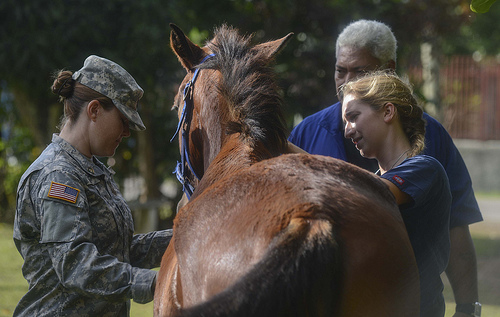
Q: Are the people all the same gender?
A: No, they are both male and female.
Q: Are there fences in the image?
A: Yes, there is a fence.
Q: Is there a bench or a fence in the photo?
A: Yes, there is a fence.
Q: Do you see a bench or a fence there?
A: Yes, there is a fence.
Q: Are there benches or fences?
A: Yes, there is a fence.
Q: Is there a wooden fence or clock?
A: Yes, there is a wood fence.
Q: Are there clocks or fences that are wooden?
A: Yes, the fence is wooden.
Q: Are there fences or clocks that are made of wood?
A: Yes, the fence is made of wood.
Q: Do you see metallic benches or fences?
A: Yes, there is a metal fence.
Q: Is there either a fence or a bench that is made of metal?
A: Yes, the fence is made of metal.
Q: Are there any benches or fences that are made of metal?
A: Yes, the fence is made of metal.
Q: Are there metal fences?
A: Yes, there is a fence that is made of metal.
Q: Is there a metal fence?
A: Yes, there is a fence that is made of metal.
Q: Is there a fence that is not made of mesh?
A: Yes, there is a fence that is made of metal.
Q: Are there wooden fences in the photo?
A: Yes, there is a wood fence.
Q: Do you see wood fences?
A: Yes, there is a wood fence.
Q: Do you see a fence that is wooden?
A: Yes, there is a fence that is wooden.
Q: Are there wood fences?
A: Yes, there is a fence that is made of wood.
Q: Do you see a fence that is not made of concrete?
A: Yes, there is a fence that is made of wood.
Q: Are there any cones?
A: No, there are no cones.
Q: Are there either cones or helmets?
A: No, there are no cones or helmets.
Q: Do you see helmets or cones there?
A: No, there are no cones or helmets.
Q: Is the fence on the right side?
A: Yes, the fence is on the right of the image.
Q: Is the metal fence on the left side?
A: No, the fence is on the right of the image.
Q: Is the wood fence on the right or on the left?
A: The fence is on the right of the image.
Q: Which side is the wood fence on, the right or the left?
A: The fence is on the right of the image.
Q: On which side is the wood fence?
A: The fence is on the right of the image.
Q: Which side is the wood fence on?
A: The fence is on the right of the image.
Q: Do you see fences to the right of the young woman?
A: Yes, there is a fence to the right of the woman.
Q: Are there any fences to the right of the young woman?
A: Yes, there is a fence to the right of the woman.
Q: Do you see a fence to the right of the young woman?
A: Yes, there is a fence to the right of the woman.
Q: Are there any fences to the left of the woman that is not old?
A: No, the fence is to the right of the woman.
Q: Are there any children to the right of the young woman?
A: No, there is a fence to the right of the woman.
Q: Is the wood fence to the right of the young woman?
A: Yes, the fence is to the right of the woman.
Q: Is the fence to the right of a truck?
A: No, the fence is to the right of the woman.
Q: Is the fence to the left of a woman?
A: No, the fence is to the right of a woman.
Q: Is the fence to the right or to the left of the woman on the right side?
A: The fence is to the right of the woman.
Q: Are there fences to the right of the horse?
A: Yes, there is a fence to the right of the horse.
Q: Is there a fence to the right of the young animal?
A: Yes, there is a fence to the right of the horse.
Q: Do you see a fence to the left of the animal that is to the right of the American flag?
A: No, the fence is to the right of the horse.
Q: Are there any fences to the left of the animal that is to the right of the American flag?
A: No, the fence is to the right of the horse.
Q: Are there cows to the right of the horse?
A: No, there is a fence to the right of the horse.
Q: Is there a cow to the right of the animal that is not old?
A: No, there is a fence to the right of the horse.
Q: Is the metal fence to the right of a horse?
A: Yes, the fence is to the right of a horse.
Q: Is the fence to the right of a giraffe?
A: No, the fence is to the right of a horse.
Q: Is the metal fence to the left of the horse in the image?
A: No, the fence is to the right of the horse.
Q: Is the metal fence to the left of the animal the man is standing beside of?
A: No, the fence is to the right of the horse.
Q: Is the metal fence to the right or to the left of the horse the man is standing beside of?
A: The fence is to the right of the horse.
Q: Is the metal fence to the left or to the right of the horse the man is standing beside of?
A: The fence is to the right of the horse.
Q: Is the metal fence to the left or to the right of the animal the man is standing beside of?
A: The fence is to the right of the horse.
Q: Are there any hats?
A: Yes, there is a hat.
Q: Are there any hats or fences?
A: Yes, there is a hat.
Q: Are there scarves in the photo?
A: No, there are no scarves.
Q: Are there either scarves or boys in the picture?
A: No, there are no scarves or boys.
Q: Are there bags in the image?
A: No, there are no bags.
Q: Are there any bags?
A: No, there are no bags.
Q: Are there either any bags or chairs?
A: No, there are no bags or chairs.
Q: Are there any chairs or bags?
A: No, there are no bags or chairs.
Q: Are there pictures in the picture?
A: No, there are no pictures.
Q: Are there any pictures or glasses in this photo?
A: No, there are no pictures or glasses.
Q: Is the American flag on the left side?
A: Yes, the American flag is on the left of the image.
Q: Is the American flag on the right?
A: No, the American flag is on the left of the image.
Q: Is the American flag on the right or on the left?
A: The American flag is on the left of the image.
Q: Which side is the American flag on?
A: The American flag is on the left of the image.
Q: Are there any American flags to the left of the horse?
A: Yes, there is an American flag to the left of the horse.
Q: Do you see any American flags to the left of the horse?
A: Yes, there is an American flag to the left of the horse.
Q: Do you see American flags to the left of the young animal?
A: Yes, there is an American flag to the left of the horse.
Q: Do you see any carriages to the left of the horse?
A: No, there is an American flag to the left of the horse.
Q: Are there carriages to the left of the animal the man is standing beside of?
A: No, there is an American flag to the left of the horse.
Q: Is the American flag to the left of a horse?
A: Yes, the American flag is to the left of a horse.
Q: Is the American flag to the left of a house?
A: No, the American flag is to the left of a horse.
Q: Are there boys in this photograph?
A: No, there are no boys.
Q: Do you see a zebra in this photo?
A: No, there are no zebras.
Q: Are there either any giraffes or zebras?
A: No, there are no zebras or giraffes.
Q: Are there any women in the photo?
A: Yes, there is a woman.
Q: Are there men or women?
A: Yes, there is a woman.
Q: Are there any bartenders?
A: No, there are no bartenders.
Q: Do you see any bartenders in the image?
A: No, there are no bartenders.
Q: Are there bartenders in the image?
A: No, there are no bartenders.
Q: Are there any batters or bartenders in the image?
A: No, there are no bartenders or batters.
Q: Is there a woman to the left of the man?
A: Yes, there is a woman to the left of the man.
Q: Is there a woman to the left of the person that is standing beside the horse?
A: Yes, there is a woman to the left of the man.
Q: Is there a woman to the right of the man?
A: No, the woman is to the left of the man.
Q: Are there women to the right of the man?
A: No, the woman is to the left of the man.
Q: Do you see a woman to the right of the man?
A: No, the woman is to the left of the man.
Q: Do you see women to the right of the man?
A: No, the woman is to the left of the man.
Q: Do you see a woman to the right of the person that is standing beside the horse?
A: No, the woman is to the left of the man.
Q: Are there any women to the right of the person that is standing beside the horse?
A: No, the woman is to the left of the man.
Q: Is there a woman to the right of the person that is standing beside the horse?
A: No, the woman is to the left of the man.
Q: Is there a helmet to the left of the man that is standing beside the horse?
A: No, there is a woman to the left of the man.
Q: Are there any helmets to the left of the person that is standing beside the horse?
A: No, there is a woman to the left of the man.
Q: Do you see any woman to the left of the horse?
A: Yes, there is a woman to the left of the horse.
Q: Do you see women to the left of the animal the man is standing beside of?
A: Yes, there is a woman to the left of the horse.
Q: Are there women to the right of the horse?
A: No, the woman is to the left of the horse.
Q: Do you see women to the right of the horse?
A: No, the woman is to the left of the horse.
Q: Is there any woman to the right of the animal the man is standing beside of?
A: No, the woman is to the left of the horse.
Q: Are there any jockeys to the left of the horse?
A: No, there is a woman to the left of the horse.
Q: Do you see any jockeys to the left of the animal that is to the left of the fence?
A: No, there is a woman to the left of the horse.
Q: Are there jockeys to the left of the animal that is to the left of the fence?
A: No, there is a woman to the left of the horse.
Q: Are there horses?
A: Yes, there is a horse.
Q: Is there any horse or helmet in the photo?
A: Yes, there is a horse.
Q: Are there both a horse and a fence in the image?
A: Yes, there are both a horse and a fence.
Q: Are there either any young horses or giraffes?
A: Yes, there is a young horse.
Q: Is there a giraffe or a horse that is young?
A: Yes, the horse is young.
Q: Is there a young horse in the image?
A: Yes, there is a young horse.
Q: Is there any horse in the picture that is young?
A: Yes, there is a horse that is young.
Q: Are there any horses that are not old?
A: Yes, there is an young horse.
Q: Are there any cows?
A: No, there are no cows.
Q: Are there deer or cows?
A: No, there are no cows or deer.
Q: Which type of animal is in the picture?
A: The animal is a horse.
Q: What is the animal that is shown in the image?
A: The animal is a horse.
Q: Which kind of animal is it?
A: The animal is a horse.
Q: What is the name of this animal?
A: This is a horse.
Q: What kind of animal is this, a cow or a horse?
A: This is a horse.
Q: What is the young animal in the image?
A: The animal is a horse.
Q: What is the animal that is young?
A: The animal is a horse.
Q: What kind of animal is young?
A: The animal is a horse.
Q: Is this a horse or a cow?
A: This is a horse.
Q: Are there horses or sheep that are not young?
A: No, there is a horse but it is young.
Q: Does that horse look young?
A: Yes, the horse is young.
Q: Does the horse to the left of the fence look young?
A: Yes, the horse is young.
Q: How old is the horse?
A: The horse is young.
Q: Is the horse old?
A: No, the horse is young.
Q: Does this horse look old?
A: No, the horse is young.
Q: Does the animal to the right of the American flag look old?
A: No, the horse is young.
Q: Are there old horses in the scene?
A: No, there is a horse but it is young.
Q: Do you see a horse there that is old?
A: No, there is a horse but it is young.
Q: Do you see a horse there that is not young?
A: No, there is a horse but it is young.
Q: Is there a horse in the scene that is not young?
A: No, there is a horse but it is young.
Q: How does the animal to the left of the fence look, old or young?
A: The horse is young.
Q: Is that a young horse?
A: Yes, that is a young horse.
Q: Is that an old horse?
A: No, that is a young horse.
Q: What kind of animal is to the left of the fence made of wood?
A: The animal is a horse.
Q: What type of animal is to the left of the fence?
A: The animal is a horse.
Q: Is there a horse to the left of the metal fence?
A: Yes, there is a horse to the left of the fence.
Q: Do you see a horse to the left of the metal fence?
A: Yes, there is a horse to the left of the fence.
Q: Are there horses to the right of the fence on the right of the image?
A: No, the horse is to the left of the fence.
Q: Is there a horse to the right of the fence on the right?
A: No, the horse is to the left of the fence.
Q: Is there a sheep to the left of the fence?
A: No, there is a horse to the left of the fence.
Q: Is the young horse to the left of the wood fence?
A: Yes, the horse is to the left of the fence.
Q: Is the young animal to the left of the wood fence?
A: Yes, the horse is to the left of the fence.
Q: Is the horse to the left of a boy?
A: No, the horse is to the left of the fence.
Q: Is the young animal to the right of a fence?
A: No, the horse is to the left of a fence.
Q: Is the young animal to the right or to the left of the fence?
A: The horse is to the left of the fence.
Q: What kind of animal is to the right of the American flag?
A: The animal is a horse.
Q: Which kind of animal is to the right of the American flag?
A: The animal is a horse.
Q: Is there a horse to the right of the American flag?
A: Yes, there is a horse to the right of the American flag.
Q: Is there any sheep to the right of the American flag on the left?
A: No, there is a horse to the right of the American flag.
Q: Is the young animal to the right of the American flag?
A: Yes, the horse is to the right of the American flag.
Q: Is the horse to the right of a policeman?
A: No, the horse is to the right of the American flag.